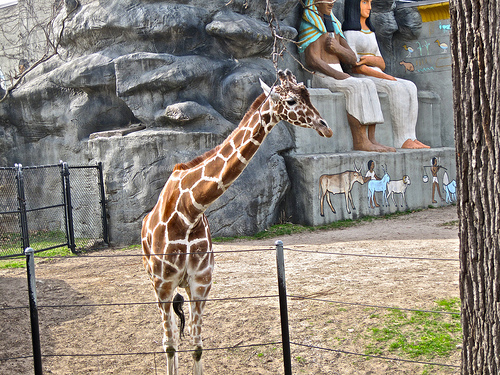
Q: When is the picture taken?
A: Day time.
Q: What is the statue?
A: Egyptian people.